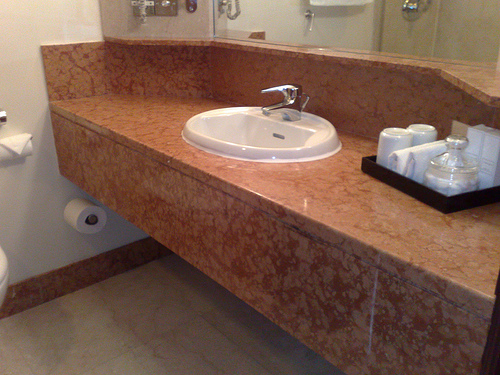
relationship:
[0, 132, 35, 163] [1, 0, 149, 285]
toilet paper attached to wall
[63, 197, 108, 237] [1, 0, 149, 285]
toilet paper attached to wall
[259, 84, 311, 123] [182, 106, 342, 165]
faucet inside sink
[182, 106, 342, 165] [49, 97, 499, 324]
sink inside counter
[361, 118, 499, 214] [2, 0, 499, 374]
amenities inside restroom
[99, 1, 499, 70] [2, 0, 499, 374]
mirror in restroom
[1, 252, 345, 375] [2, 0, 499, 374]
floor inside restroom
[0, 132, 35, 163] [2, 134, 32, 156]
toilet paper has flip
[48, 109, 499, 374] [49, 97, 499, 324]
front of counter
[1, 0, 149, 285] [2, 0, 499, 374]
wall inside restroom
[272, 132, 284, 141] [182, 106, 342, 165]
hole inside sink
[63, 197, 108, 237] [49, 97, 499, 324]
toilet paper underneath counter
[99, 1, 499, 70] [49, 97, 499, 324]
mirror above counter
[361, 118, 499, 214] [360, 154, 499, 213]
amenities inside tray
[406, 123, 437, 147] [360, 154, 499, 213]
cup inside tray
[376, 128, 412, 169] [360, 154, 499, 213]
cup inside tray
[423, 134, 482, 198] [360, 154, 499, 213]
jar inside tray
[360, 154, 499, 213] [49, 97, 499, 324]
tray on counter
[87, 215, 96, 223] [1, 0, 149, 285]
handle mounted on wall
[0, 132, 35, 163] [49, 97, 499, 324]
toilet paper under counter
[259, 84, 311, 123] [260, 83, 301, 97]
faucet has handle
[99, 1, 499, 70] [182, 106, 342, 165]
mirror above sink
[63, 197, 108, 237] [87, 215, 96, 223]
toilet paper placed on handle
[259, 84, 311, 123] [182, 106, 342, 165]
faucet attached to sink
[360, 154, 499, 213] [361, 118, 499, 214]
tray contains amenities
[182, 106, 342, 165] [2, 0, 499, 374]
sink inside restroom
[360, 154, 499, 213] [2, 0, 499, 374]
tray inside restroom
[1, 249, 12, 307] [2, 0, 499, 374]
toilet inside restroom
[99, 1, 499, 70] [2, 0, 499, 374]
mirror inside restroom